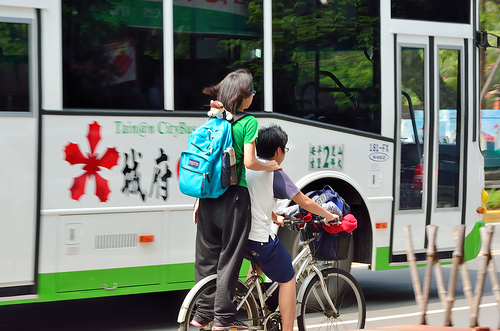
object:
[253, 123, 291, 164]
head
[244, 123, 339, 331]
man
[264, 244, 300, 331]
leg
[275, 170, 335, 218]
arm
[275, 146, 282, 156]
ear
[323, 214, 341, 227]
hand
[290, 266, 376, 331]
wheel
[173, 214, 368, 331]
bicycle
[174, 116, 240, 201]
backpack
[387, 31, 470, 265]
doors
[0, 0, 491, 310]
bus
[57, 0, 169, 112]
window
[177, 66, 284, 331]
kid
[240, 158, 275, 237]
back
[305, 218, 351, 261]
basket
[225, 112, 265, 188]
shirt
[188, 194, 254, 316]
pants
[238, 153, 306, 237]
shirt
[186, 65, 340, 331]
people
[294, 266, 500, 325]
street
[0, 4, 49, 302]
door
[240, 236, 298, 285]
shorts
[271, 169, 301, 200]
sleeves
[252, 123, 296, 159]
hair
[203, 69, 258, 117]
hair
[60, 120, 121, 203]
symbol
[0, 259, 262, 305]
green color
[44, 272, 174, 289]
green color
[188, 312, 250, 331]
sneakers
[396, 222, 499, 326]
sticks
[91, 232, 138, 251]
vents